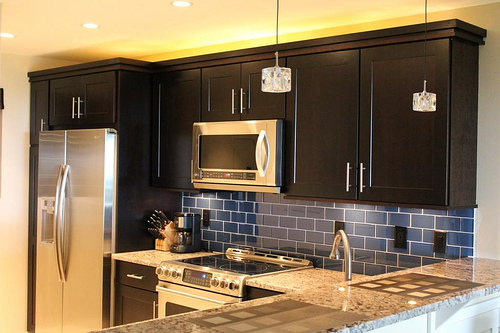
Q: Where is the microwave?
A: Over the stove.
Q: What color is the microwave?
A: Silver and black.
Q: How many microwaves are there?
A: One.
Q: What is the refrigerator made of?
A: Metal.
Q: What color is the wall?
A: Blue and white.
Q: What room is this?
A: Kitchen.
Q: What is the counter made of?
A: Marble.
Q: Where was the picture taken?
A: In the kitchen.